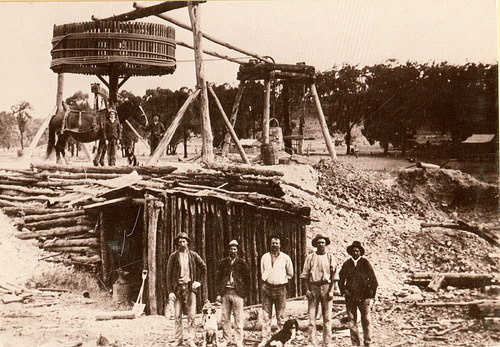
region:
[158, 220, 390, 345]
MEN STANDING IN FRONT OF MINE SHAFT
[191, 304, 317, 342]
TWO DOGS IN FRONT OF MEN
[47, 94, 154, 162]
MULE USED FOR HAULING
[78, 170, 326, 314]
ENTRANCE TO MINE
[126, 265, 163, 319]
SHOVEL LEANING AGAINST MINE SHAFT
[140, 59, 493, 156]
TREES AT THE SKYLINE IN BACKGROUND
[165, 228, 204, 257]
MAN HAS HAT ON HEAD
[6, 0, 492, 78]
CLEAR SKY IN BACKGROUND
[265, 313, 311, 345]
DOG'S COAT IS TWO DIFFERENT COLORS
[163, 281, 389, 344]
MEN ARE WEARING JEANS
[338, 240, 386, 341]
this is a person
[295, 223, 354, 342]
this is a person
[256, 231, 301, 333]
this is a person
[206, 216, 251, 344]
this is a person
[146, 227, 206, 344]
this is a person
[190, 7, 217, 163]
this is a post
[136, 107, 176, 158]
this is a person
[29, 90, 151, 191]
this is a horse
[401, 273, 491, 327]
this is dirt on the ground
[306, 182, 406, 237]
this is dirt on the ground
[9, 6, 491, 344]
a scene outside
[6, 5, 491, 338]
a black and white photo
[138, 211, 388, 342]
a group of people posing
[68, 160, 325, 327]
a log shack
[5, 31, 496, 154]
trees in the back ground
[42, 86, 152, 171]
a horse in the distance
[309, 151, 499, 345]
a rocky ground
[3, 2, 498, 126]
a gray sky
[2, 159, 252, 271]
some logs near shack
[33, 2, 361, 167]
a wooden tower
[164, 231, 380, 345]
group of men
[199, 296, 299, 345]
some dogs standing by men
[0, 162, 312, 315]
log covered mine shaft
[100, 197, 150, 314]
mine shaft entrance way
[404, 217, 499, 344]
scattered timber on the ground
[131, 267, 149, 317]
shovel leaning against entrance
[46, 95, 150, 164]
black horse holding supplies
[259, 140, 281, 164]
a wooden barrel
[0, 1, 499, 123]
wide clear skyline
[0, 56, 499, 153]
long line of trees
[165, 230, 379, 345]
group of men posing for a photo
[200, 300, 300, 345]
a few dogs looking at the camera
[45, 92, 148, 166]
a saddled black horse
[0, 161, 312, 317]
log covered mine entrance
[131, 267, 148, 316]
Shovel leaning against entranceway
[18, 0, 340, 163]
some wooden contraption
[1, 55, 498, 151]
a long tree line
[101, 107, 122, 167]
man standing straight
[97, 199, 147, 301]
opening to a mine shaft